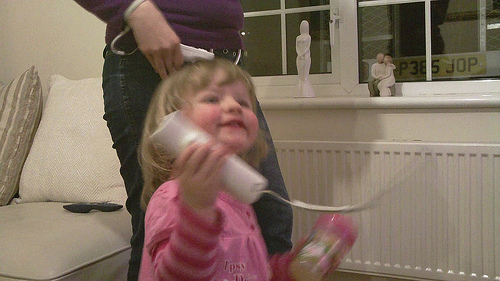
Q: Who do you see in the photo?
A: A little girl and part of her mom.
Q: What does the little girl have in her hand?
A: A Wii remote.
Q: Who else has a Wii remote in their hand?
A: The little girl's mom.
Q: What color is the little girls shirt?
A: Pink.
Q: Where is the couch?
A: Behind the little girl and her mom.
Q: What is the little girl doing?
A: Playing Wii.